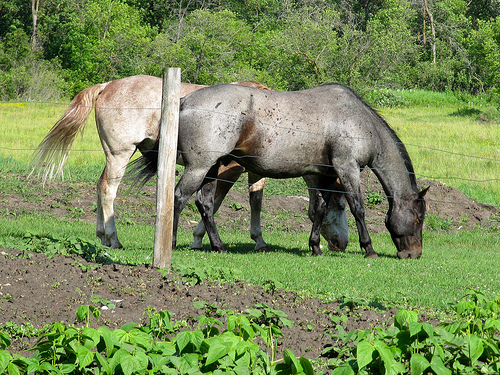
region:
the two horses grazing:
[31, 69, 431, 264]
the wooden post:
[153, 65, 182, 268]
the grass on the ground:
[235, 255, 472, 287]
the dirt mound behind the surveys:
[213, 160, 494, 239]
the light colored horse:
[28, 76, 346, 251]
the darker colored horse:
[165, 82, 425, 261]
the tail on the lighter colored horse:
[28, 83, 90, 175]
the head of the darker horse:
[389, 189, 425, 264]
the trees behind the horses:
[30, 2, 481, 82]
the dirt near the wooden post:
[18, 250, 245, 325]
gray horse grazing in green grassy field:
[123, 74, 426, 265]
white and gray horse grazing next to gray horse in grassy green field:
[26, 71, 368, 263]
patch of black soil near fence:
[1, 236, 465, 374]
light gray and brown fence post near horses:
[151, 60, 184, 276]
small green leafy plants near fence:
[1, 289, 498, 373]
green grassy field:
[1, 93, 497, 317]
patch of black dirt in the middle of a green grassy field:
[0, 154, 497, 236]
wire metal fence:
[0, 61, 497, 278]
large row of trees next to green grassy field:
[0, 0, 499, 114]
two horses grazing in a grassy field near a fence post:
[23, 57, 437, 271]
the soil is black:
[297, 306, 304, 323]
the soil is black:
[284, 313, 295, 343]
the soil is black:
[296, 333, 307, 353]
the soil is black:
[303, 338, 308, 352]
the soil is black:
[304, 301, 313, 333]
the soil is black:
[299, 340, 308, 355]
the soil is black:
[304, 333, 314, 345]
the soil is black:
[307, 346, 315, 351]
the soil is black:
[290, 331, 301, 351]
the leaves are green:
[414, 325, 424, 347]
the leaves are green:
[388, 337, 398, 357]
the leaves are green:
[403, 340, 416, 343]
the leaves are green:
[390, 320, 398, 350]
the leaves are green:
[402, 332, 404, 353]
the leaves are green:
[411, 350, 417, 360]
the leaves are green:
[405, 337, 416, 368]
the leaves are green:
[407, 335, 416, 347]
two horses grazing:
[25, 74, 432, 264]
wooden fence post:
[152, 64, 181, 267]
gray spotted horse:
[124, 81, 431, 260]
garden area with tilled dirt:
[7, 247, 498, 374]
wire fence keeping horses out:
[2, 66, 497, 275]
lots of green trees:
[3, 2, 495, 102]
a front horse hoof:
[364, 249, 379, 260]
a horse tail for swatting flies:
[25, 82, 105, 190]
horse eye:
[415, 211, 426, 224]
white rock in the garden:
[101, 304, 110, 309]